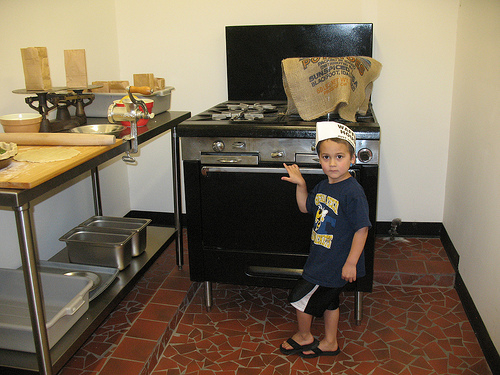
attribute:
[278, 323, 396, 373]
flip flops — black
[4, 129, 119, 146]
dough — white, rolled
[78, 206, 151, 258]
pots — silver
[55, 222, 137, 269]
pots — silver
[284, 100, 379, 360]
boy — casually dressed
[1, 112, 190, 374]
table — kitchen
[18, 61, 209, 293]
table — metal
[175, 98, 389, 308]
stove — gas, black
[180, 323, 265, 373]
floor — red, stone, mosaic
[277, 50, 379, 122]
sack — printed, burlap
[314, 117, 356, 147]
hat — paper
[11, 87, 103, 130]
scale — metal, old fashioned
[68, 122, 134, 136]
pan — metal, pie